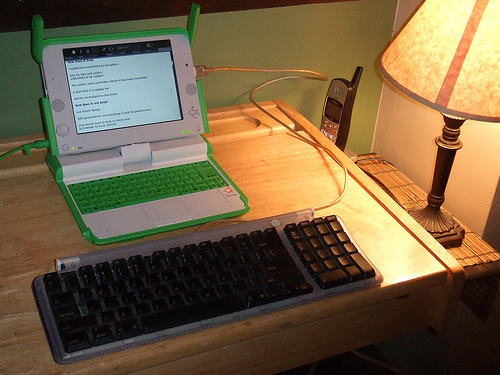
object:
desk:
[1, 99, 466, 374]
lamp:
[377, 0, 499, 247]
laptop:
[29, 4, 253, 247]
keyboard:
[32, 207, 386, 367]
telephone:
[319, 65, 365, 152]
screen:
[62, 39, 184, 136]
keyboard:
[68, 161, 228, 215]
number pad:
[284, 214, 377, 290]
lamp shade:
[377, 0, 499, 124]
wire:
[0, 137, 48, 160]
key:
[61, 331, 92, 353]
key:
[89, 323, 116, 346]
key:
[113, 319, 142, 337]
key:
[242, 292, 259, 308]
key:
[55, 313, 99, 335]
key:
[97, 309, 119, 325]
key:
[115, 305, 135, 322]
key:
[131, 301, 152, 317]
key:
[152, 299, 168, 312]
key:
[168, 293, 188, 310]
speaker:
[184, 81, 198, 96]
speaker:
[50, 96, 66, 113]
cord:
[195, 63, 349, 215]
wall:
[1, 0, 400, 157]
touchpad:
[141, 197, 192, 224]